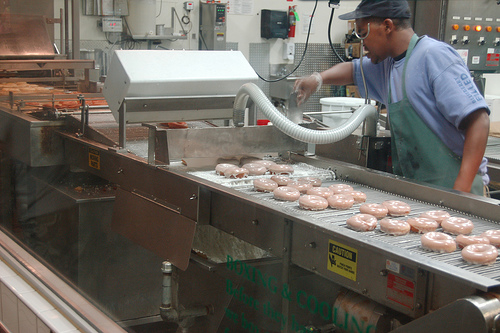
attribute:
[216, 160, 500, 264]
donuts — glazed, white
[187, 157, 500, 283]
tray — moving, silver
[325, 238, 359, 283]
warning sticker — yellow, black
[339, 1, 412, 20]
cap — dark, black, blue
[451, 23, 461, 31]
button — orange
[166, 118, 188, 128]
donut — unglazed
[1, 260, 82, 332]
tiles — white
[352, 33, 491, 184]
shirt — light blue, blue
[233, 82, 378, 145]
hose — light gray, white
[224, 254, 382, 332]
writing — green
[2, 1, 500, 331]
window — glass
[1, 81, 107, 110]
donuts — brown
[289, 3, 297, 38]
fire extinguisher — red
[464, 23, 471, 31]
button — yellow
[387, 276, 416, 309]
sign — red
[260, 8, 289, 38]
box — black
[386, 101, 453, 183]
apron — green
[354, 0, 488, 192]
man — standing, working, making donuts